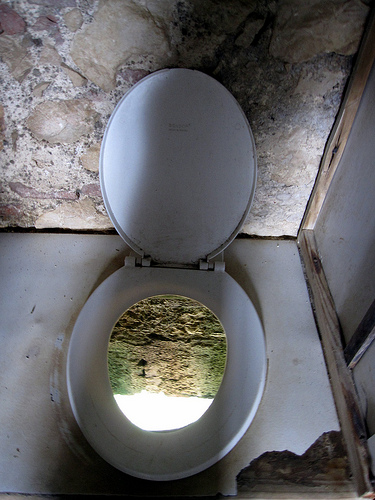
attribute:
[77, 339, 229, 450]
seat — white, plastic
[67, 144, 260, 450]
toilet — side, edge, part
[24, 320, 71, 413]
surface — white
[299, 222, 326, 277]
frame — wooden, wood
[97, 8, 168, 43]
wall — part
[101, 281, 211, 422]
cover — open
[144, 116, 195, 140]
name — faded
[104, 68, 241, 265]
lid — plastic, white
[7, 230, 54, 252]
space — part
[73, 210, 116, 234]
stone — large, part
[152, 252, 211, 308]
hinge — white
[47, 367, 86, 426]
paint — chipped